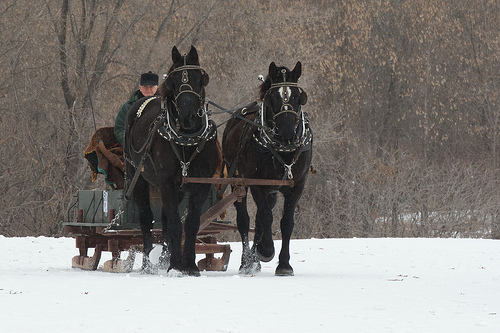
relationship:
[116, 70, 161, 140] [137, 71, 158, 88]
man in cap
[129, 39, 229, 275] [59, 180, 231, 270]
horse pulling sled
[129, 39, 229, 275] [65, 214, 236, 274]
horse pulling sled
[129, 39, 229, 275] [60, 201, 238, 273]
horse pulling sled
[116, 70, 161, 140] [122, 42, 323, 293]
man with horses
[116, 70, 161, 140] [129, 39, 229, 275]
man with horse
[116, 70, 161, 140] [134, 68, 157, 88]
man wearing cap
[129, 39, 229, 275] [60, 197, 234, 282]
horse pulling sled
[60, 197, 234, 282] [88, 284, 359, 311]
sled in snow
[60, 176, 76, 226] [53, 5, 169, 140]
trunks on tree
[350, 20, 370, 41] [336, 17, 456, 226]
leaves on tree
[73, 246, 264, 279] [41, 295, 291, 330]
vehicle covered snow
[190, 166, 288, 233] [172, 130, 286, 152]
bars around neck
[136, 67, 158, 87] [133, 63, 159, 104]
cap on head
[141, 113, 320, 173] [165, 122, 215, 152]
reins on neck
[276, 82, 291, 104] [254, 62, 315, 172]
spot on head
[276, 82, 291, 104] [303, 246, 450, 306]
spot on snow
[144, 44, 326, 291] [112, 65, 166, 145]
horses driven man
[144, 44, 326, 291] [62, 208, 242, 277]
horses pulling sled